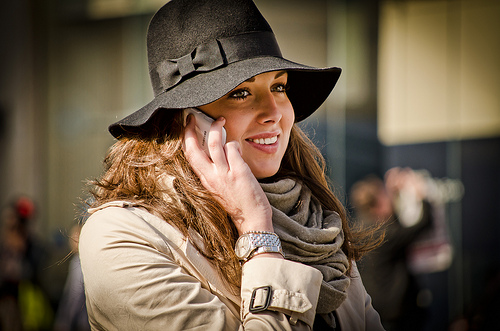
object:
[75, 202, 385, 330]
coat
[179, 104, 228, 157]
phone ear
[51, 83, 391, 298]
hair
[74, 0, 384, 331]
lady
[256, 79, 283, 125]
nose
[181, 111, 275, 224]
hand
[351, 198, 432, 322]
jacket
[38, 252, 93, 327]
jacket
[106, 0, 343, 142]
cap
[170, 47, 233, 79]
black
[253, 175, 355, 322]
scarf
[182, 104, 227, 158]
cell phone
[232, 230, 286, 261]
watch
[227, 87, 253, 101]
eye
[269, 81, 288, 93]
eye